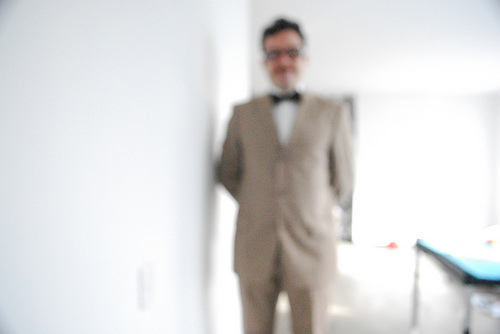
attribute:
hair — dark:
[254, 8, 312, 46]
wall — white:
[35, 90, 202, 215]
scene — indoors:
[7, 33, 489, 330]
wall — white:
[49, 78, 185, 203]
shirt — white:
[270, 84, 302, 144]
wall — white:
[1, 2, 250, 332]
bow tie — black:
[265, 81, 310, 118]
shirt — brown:
[209, 81, 396, 190]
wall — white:
[63, 157, 118, 279]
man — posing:
[201, 27, 346, 214]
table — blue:
[411, 239, 493, 321]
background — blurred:
[378, 85, 469, 171]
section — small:
[6, 155, 41, 222]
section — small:
[3, 261, 42, 301]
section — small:
[58, 77, 428, 167]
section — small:
[110, 238, 195, 285]